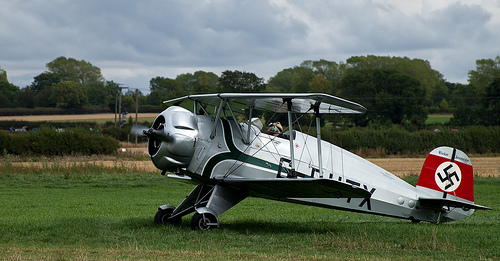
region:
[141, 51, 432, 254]
a plane on the ground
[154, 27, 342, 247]
an airplan eon the ground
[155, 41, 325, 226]
a small airplane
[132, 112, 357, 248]
a small plane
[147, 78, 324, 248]
a small airplane on the ground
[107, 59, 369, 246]
a small plane on the ground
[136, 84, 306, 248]
a white plane on the ground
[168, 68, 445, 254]
a small airplane on the ground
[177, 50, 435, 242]
a small white airplane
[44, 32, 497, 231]
a German aircraft in the photo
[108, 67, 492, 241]
this German airplane was used during World War II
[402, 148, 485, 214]
a swastika is on the back of the plane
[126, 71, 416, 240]
the plane is silver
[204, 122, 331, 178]
it has a green stripe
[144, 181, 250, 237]
the landing gear on the plane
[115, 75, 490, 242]
this is a fighter plane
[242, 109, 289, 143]
a pilot is in the plane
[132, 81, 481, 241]
the plane has been well preserved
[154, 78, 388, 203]
this plane is a bilane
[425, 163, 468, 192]
Nazi swatstika symbol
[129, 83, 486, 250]
Old German plane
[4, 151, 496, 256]
Grassy field where plane has landed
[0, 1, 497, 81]
Storm clouds on the horizon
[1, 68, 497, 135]
Trees off in the distance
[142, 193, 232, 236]
Two wheels of the airplane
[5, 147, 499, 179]
Sand beyond the plane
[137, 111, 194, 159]
Plane is missing the propeller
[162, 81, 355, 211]
Wings of the plane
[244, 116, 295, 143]
Person sitting in cockpit of the plane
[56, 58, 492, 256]
a world war II german plane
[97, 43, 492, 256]
a nazi german plane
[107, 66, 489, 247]
a nazi war plane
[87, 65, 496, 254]
plane with a nazi symbol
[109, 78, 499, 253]
plane with a swastika on the tale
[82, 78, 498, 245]
a historical world war two plane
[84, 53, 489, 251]
a historical world war two nazi plane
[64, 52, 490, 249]
a historical world war two nazi airplane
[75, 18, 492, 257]
a nazi world war two aircraft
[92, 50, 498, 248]
a German world war two aircraft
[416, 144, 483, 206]
tail fin of an airplane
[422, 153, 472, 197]
a swastika on a tail fin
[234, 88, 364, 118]
the left wing of a biplane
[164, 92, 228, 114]
the right wing of a plane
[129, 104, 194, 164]
the prop on an airplane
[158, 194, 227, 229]
airplane landing gear on the grass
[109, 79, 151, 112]
electrical power poles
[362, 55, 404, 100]
trees with green leaves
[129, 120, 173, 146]
the propeller on an airplane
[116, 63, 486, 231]
a grey and green airplane